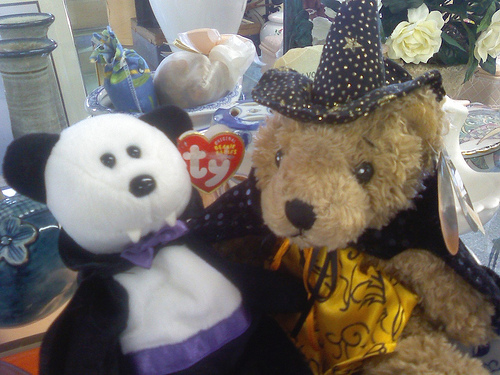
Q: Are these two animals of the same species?
A: Yes, all the animals are bears.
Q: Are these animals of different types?
A: No, all the animals are bears.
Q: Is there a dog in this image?
A: No, there are no dogs.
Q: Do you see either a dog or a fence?
A: No, there are no dogs or fences.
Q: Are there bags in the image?
A: Yes, there is a bag.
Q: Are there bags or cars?
A: Yes, there is a bag.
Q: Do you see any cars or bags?
A: Yes, there is a bag.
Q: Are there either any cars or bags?
A: Yes, there is a bag.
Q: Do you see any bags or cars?
A: Yes, there is a bag.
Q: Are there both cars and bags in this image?
A: No, there is a bag but no cars.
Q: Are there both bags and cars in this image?
A: No, there is a bag but no cars.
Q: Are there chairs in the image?
A: No, there are no chairs.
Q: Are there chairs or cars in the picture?
A: No, there are no chairs or cars.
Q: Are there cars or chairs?
A: No, there are no chairs or cars.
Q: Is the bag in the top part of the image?
A: Yes, the bag is in the top of the image.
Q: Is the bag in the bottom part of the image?
A: No, the bag is in the top of the image.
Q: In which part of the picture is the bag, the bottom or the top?
A: The bag is in the top of the image.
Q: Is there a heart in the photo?
A: Yes, there is a heart.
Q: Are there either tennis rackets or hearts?
A: Yes, there is a heart.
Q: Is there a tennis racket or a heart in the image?
A: Yes, there is a heart.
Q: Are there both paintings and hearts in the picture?
A: No, there is a heart but no paintings.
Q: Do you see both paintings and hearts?
A: No, there is a heart but no paintings.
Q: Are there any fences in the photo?
A: No, there are no fences.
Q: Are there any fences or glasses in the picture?
A: No, there are no fences or glasses.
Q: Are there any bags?
A: Yes, there is a bag.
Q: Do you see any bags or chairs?
A: Yes, there is a bag.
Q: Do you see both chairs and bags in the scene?
A: No, there is a bag but no chairs.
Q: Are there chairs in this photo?
A: No, there are no chairs.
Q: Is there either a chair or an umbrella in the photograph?
A: No, there are no chairs or umbrellas.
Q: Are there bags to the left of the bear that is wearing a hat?
A: Yes, there is a bag to the left of the bear.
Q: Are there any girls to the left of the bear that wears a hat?
A: No, there is a bag to the left of the bear.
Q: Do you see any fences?
A: No, there are no fences.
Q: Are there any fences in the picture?
A: No, there are no fences.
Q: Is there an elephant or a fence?
A: No, there are no fences or elephants.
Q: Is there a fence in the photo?
A: No, there are no fences.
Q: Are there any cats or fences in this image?
A: No, there are no fences or cats.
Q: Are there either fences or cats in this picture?
A: No, there are no fences or cats.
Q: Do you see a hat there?
A: Yes, there is a hat.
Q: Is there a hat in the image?
A: Yes, there is a hat.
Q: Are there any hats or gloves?
A: Yes, there is a hat.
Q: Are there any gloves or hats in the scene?
A: Yes, there is a hat.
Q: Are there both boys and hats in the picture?
A: No, there is a hat but no boys.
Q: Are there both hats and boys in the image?
A: No, there is a hat but no boys.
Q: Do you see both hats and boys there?
A: No, there is a hat but no boys.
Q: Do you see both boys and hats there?
A: No, there is a hat but no boys.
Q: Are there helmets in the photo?
A: No, there are no helmets.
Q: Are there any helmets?
A: No, there are no helmets.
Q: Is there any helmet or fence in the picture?
A: No, there are no helmets or fences.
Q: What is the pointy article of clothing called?
A: The clothing item is a hat.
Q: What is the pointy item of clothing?
A: The clothing item is a hat.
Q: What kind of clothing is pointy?
A: The clothing is a hat.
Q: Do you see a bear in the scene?
A: Yes, there is a bear.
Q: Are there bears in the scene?
A: Yes, there is a bear.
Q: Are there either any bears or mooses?
A: Yes, there is a bear.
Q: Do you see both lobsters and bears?
A: No, there is a bear but no lobsters.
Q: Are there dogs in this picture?
A: No, there are no dogs.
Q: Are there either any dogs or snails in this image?
A: No, there are no dogs or snails.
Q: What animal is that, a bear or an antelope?
A: That is a bear.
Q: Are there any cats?
A: No, there are no cats.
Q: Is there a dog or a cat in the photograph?
A: No, there are no cats or dogs.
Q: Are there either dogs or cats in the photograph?
A: No, there are no cats or dogs.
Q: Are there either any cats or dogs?
A: No, there are no cats or dogs.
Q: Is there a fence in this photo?
A: No, there are no fences.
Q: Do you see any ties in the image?
A: Yes, there is a tie.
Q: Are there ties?
A: Yes, there is a tie.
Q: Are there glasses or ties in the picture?
A: Yes, there is a tie.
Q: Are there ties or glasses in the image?
A: Yes, there is a tie.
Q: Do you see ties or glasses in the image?
A: Yes, there is a tie.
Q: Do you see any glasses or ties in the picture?
A: Yes, there is a tie.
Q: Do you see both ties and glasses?
A: No, there is a tie but no glasses.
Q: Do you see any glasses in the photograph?
A: No, there are no glasses.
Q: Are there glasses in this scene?
A: No, there are no glasses.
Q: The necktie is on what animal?
A: The necktie is on the bear.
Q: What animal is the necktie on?
A: The necktie is on the bear.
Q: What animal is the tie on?
A: The necktie is on the bear.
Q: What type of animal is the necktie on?
A: The necktie is on the bear.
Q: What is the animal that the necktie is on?
A: The animal is a bear.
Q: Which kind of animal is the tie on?
A: The necktie is on the bear.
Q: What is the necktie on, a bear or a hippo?
A: The necktie is on a bear.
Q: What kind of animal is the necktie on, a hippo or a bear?
A: The necktie is on a bear.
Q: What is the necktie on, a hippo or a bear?
A: The necktie is on a bear.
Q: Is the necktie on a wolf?
A: No, the necktie is on the bear.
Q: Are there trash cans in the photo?
A: No, there are no trash cans.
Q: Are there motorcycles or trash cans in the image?
A: No, there are no trash cans or motorcycles.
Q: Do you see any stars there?
A: Yes, there is a star.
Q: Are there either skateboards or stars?
A: Yes, there is a star.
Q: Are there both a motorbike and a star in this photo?
A: No, there is a star but no motorcycles.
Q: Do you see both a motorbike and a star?
A: No, there is a star but no motorcycles.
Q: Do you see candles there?
A: No, there are no candles.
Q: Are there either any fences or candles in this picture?
A: No, there are no candles or fences.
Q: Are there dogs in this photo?
A: No, there are no dogs.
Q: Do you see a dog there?
A: No, there are no dogs.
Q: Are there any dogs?
A: No, there are no dogs.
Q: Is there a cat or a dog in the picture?
A: No, there are no dogs or cats.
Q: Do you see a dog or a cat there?
A: No, there are no dogs or cats.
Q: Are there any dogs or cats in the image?
A: No, there are no dogs or cats.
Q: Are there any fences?
A: No, there are no fences.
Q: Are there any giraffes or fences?
A: No, there are no fences or giraffes.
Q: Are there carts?
A: No, there are no carts.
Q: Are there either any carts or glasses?
A: No, there are no carts or glasses.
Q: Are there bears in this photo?
A: Yes, there is a bear.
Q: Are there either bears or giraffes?
A: Yes, there is a bear.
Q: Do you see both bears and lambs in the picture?
A: No, there is a bear but no lambs.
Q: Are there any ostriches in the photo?
A: No, there are no ostriches.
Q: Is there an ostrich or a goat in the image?
A: No, there are no ostriches or goats.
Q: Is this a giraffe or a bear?
A: This is a bear.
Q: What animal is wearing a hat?
A: The bear is wearing a hat.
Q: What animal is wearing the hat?
A: The bear is wearing a hat.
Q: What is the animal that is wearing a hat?
A: The animal is a bear.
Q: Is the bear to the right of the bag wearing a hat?
A: Yes, the bear is wearing a hat.